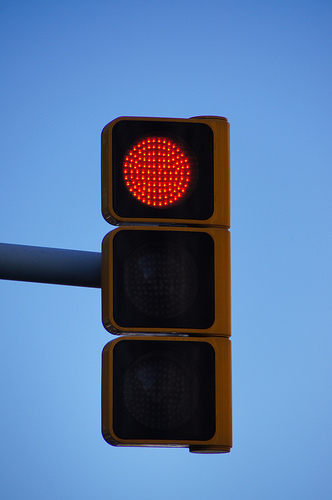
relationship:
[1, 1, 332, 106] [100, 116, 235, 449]
blue sky behind traffic light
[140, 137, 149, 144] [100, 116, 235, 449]
pixel on traffic light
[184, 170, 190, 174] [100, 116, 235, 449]
pixel on traffic light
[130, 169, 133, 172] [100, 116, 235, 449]
pixel on traffic light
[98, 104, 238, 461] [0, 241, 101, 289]
light attached to a pole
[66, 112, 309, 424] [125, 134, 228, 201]
signal with light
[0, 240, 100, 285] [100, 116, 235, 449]
bar of a traffic light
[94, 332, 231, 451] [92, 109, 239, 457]
bottom of a traffic light